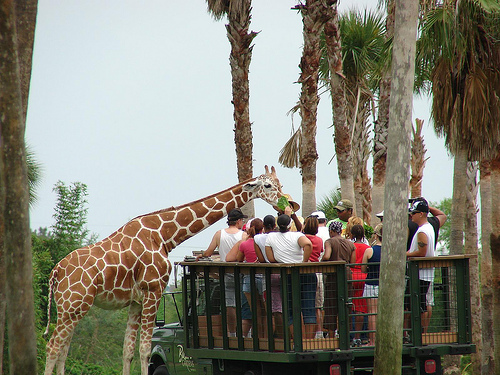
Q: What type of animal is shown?
A: Giraffe.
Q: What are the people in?
A: A platform with railing.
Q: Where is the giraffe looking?
A: Toward the people.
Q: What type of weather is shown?
A: Clear.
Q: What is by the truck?
A: Giraffe.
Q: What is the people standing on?
A: Wooden deck.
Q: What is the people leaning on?
A: Painted fence.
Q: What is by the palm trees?
A: People on deck.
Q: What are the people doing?
A: Looking at giraffe.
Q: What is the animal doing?
A: Giraffe eating.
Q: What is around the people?
A: Safety cage.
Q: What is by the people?
A: Palm tree.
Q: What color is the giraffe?
A: Brown.